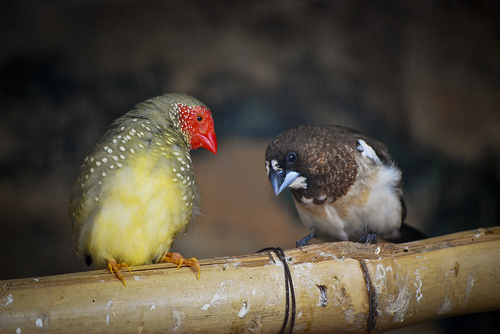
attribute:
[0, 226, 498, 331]
pole — brown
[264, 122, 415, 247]
bird — brown and white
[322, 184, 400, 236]
feathers — tan